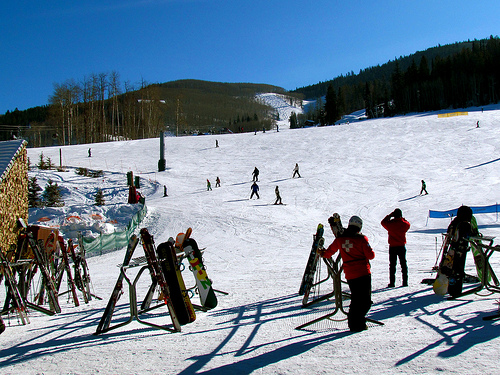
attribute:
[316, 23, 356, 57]
cloud — white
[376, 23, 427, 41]
cloud — white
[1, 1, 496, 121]
sky — blue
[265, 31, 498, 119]
evergreen trees —  line , tall 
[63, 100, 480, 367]
slope — snowy ski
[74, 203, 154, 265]
wall — green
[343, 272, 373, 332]
pants — dark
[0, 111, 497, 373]
ski slope —  snowy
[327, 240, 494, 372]
ski slope — snowy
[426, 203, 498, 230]
banner — blue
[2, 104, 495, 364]
snow — tall, white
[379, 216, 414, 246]
jacket — winter, red 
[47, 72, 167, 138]
trees —  leafless, brown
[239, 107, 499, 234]
ski slope — snowy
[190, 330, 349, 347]
snow — white 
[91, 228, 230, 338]
rack — snowboards,  skis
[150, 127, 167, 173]
pole — black, upright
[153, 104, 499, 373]
ski slope — snowy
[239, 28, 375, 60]
clouds — white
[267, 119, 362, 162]
slope —  for ski,  snowy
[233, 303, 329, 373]
shadows — black 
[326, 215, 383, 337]
person — standing